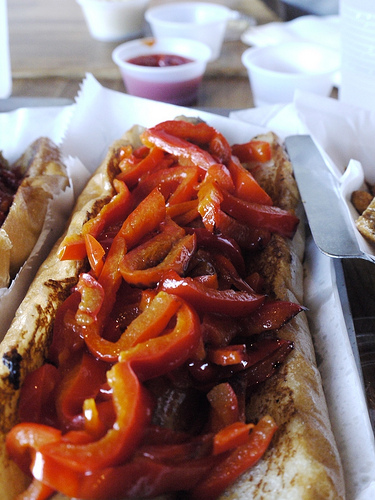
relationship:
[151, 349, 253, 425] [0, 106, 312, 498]
sacuce on hot dog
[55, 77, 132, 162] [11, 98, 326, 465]
wrapper under hot dog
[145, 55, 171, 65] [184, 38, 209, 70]
ketchup in cup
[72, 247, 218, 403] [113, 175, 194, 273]
red pepper next to red pepper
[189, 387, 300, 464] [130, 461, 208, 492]
pepper next to pepper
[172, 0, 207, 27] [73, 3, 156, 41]
something in cup